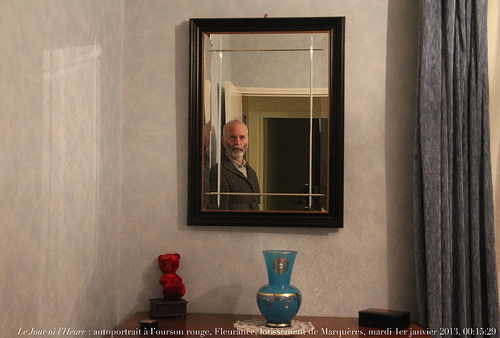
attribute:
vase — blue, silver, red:
[256, 245, 301, 323]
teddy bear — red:
[157, 250, 186, 296]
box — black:
[354, 305, 413, 330]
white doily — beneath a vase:
[235, 312, 318, 334]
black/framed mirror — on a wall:
[186, 12, 347, 232]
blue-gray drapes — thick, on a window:
[411, 1, 482, 335]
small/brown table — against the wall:
[116, 309, 427, 336]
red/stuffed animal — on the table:
[156, 248, 186, 298]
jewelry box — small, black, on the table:
[356, 304, 413, 334]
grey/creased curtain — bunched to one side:
[413, 0, 478, 335]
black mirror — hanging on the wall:
[184, 13, 347, 231]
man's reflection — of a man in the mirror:
[206, 118, 268, 209]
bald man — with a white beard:
[218, 115, 252, 160]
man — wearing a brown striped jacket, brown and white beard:
[205, 116, 265, 216]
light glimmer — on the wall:
[41, 43, 140, 327]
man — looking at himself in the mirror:
[211, 118, 267, 216]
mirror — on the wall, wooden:
[200, 30, 328, 210]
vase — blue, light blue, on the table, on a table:
[254, 245, 304, 330]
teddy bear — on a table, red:
[156, 251, 186, 302]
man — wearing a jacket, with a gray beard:
[206, 115, 267, 206]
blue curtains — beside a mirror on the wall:
[411, 30, 482, 333]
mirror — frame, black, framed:
[185, 11, 346, 231]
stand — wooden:
[104, 306, 434, 335]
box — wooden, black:
[354, 304, 410, 333]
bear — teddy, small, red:
[155, 248, 187, 298]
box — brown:
[143, 295, 189, 320]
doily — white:
[232, 312, 319, 331]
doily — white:
[232, 313, 317, 335]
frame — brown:
[185, 14, 346, 230]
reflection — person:
[211, 116, 262, 208]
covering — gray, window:
[414, 13, 484, 334]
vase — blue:
[256, 249, 303, 326]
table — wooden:
[119, 316, 420, 336]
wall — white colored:
[6, 41, 136, 322]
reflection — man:
[209, 118, 265, 211]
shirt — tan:
[232, 160, 250, 176]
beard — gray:
[222, 142, 251, 157]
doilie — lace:
[229, 317, 317, 336]